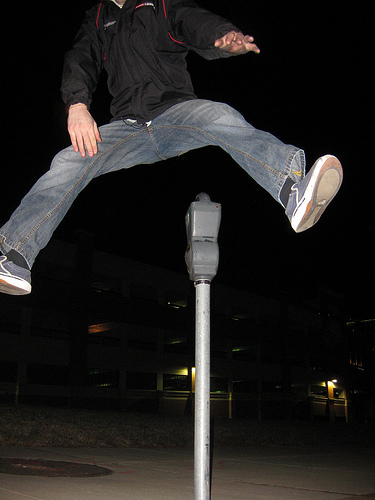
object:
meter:
[184, 191, 222, 499]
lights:
[331, 376, 340, 389]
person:
[0, 0, 343, 298]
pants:
[0, 97, 306, 268]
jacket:
[59, 0, 240, 123]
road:
[0, 442, 374, 499]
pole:
[193, 282, 212, 499]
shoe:
[283, 154, 344, 235]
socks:
[279, 175, 297, 209]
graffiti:
[11, 460, 64, 473]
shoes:
[0, 153, 345, 298]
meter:
[185, 193, 221, 285]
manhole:
[0, 458, 113, 478]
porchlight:
[184, 368, 202, 377]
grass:
[0, 412, 374, 446]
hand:
[214, 30, 260, 55]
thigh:
[167, 99, 244, 157]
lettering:
[104, 18, 118, 34]